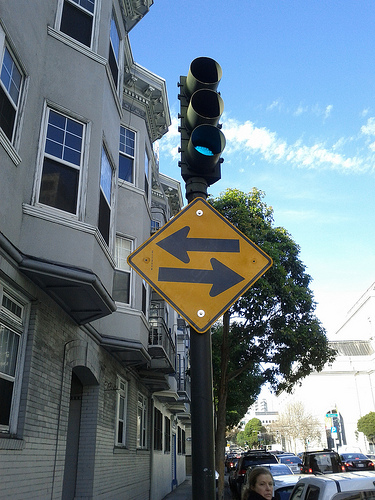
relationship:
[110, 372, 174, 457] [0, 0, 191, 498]
windows on side of building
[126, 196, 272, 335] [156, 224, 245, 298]
street sign has arrows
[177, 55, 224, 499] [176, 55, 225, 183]
sign post has traffic light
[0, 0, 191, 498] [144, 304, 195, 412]
building has balconies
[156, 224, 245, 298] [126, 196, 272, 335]
arrows on street sign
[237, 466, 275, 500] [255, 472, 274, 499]
woman has face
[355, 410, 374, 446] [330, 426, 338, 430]
tree by parking sign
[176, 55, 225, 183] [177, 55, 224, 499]
traffic light on sign post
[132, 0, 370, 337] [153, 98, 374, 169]
sky has clouds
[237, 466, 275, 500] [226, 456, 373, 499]
woman on street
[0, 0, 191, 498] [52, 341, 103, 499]
building has archway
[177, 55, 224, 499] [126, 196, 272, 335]
sign post holds street sign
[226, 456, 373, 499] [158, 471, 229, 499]
street has sidewalk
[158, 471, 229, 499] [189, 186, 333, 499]
sidewalk has trees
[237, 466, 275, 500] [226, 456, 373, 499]
woman crossing street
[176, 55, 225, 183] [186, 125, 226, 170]
traffic light with light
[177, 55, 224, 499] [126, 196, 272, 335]
sign post has street sign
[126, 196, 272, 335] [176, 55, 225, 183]
street sign under traffic light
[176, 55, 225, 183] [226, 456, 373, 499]
traffic light on street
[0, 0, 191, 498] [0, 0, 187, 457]
building has windows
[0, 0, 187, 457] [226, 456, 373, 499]
windows face street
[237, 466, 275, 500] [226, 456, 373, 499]
woman facing street